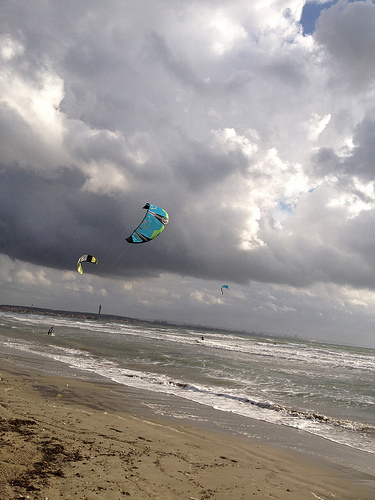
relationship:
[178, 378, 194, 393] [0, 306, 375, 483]
wave in water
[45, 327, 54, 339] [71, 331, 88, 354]
person on top of water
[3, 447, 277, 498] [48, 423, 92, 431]
sand contains tracks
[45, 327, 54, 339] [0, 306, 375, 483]
person in water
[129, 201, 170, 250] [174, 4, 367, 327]
kite in sky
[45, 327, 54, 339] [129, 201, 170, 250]
person holding kite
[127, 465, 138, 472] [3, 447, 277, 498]
footstep on top of sand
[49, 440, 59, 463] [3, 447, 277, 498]
sticks on top of sand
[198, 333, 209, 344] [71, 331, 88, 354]
man inside water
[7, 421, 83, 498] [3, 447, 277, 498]
seaweed on top of sand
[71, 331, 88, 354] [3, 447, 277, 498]
water on top of sand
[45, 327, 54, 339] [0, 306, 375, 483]
person inside water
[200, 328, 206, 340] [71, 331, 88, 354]
person inside water